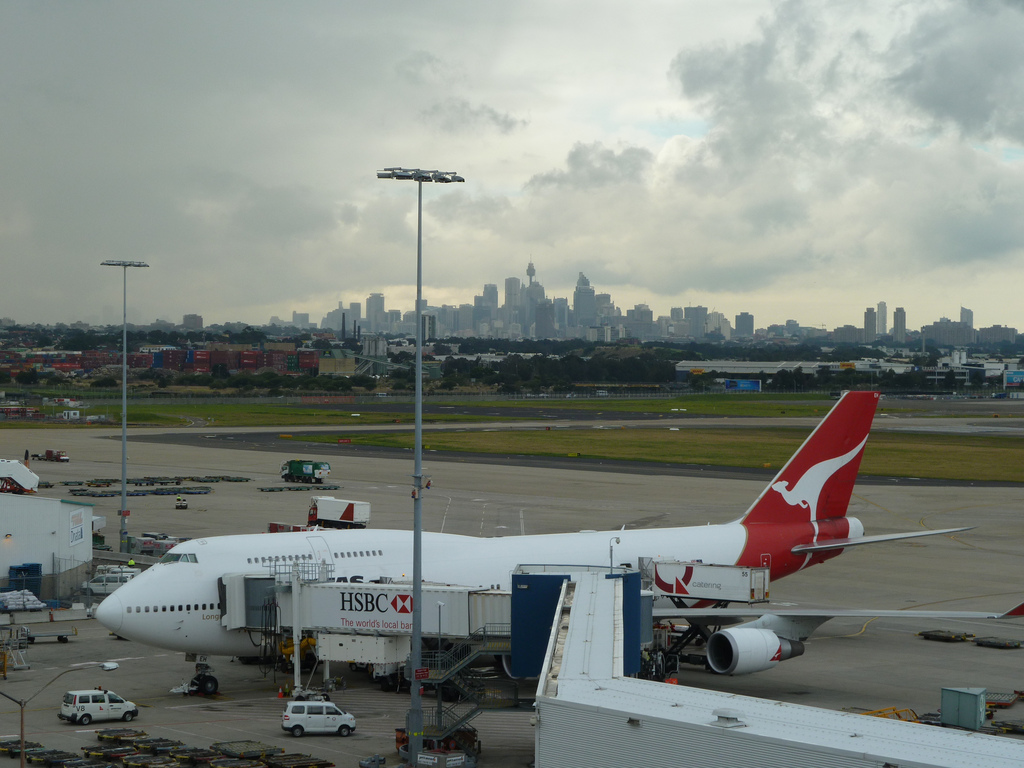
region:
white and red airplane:
[104, 374, 953, 657]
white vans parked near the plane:
[59, 674, 361, 751]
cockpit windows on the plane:
[157, 547, 205, 573]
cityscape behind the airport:
[243, 262, 1019, 360]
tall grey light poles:
[92, 158, 462, 737]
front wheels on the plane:
[181, 664, 223, 697]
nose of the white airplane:
[88, 575, 133, 642]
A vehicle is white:
[266, 686, 365, 744]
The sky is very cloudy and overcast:
[1, 0, 1016, 339]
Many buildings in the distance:
[172, 241, 1016, 349]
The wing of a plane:
[636, 589, 1016, 679]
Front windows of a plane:
[137, 533, 204, 575]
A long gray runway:
[100, 389, 1015, 443]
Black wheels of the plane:
[177, 661, 226, 704]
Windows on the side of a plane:
[235, 535, 392, 574]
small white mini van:
[274, 693, 361, 747]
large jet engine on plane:
[705, 613, 810, 681]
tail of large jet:
[745, 379, 897, 588]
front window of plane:
[154, 547, 203, 568]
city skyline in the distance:
[29, 244, 1022, 337]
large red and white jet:
[92, 385, 1020, 698]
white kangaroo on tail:
[758, 427, 864, 574]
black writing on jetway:
[334, 584, 395, 620]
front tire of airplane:
[189, 661, 222, 700]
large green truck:
[280, 455, 337, 490]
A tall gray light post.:
[373, 167, 471, 763]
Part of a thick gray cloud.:
[0, 0, 207, 121]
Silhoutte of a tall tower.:
[521, 260, 541, 281]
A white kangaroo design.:
[770, 436, 866, 572]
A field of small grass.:
[898, 440, 1015, 479]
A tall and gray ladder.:
[422, 628, 503, 758]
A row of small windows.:
[125, 600, 223, 617]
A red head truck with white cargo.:
[303, 494, 368, 526]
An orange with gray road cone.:
[275, 686, 286, 700]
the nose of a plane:
[87, 555, 163, 660]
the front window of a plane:
[134, 546, 224, 578]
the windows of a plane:
[140, 575, 216, 624]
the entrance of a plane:
[196, 569, 274, 653]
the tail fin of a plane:
[751, 373, 882, 530]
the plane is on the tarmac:
[95, 374, 1006, 676]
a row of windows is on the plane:
[122, 603, 231, 616]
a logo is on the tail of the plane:
[770, 437, 878, 556]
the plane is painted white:
[95, 392, 883, 706]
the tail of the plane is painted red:
[747, 392, 877, 586]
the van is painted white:
[283, 698, 357, 743]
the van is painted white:
[58, 689, 135, 727]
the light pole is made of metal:
[367, 156, 467, 749]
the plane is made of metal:
[93, 404, 989, 679]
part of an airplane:
[155, 547, 212, 571]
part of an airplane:
[111, 593, 223, 625]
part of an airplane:
[233, 546, 322, 572]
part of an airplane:
[326, 541, 384, 562]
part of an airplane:
[748, 383, 891, 524]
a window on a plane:
[158, 547, 168, 564]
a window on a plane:
[175, 550, 182, 566]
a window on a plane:
[186, 550, 188, 564]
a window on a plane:
[120, 607, 125, 615]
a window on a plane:
[152, 607, 159, 617]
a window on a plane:
[161, 605, 168, 613]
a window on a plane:
[174, 602, 190, 616]